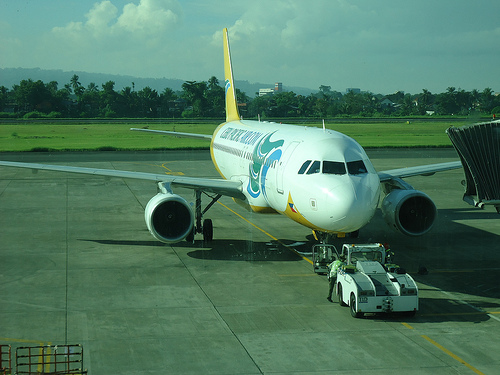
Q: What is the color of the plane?
A: White.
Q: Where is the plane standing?
A: In the ground.